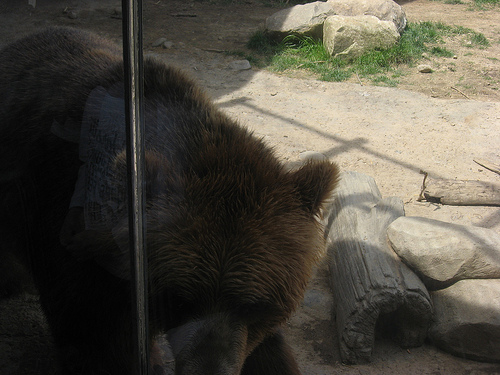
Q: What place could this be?
A: It is a zoo.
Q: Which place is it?
A: It is a zoo.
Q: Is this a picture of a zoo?
A: Yes, it is showing a zoo.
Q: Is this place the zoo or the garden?
A: It is the zoo.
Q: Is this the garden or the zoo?
A: It is the zoo.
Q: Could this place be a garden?
A: No, it is a zoo.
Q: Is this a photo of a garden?
A: No, the picture is showing a zoo.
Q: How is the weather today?
A: It is sunny.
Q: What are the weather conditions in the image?
A: It is sunny.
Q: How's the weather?
A: It is sunny.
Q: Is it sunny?
A: Yes, it is sunny.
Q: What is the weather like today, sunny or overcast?
A: It is sunny.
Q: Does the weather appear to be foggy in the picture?
A: No, it is sunny.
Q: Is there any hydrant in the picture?
A: No, there are no fire hydrants.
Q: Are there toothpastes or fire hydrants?
A: No, there are no fire hydrants or toothpastes.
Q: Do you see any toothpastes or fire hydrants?
A: No, there are no fire hydrants or toothpastes.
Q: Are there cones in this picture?
A: No, there are no cones.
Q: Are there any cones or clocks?
A: No, there are no cones or clocks.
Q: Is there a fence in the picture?
A: No, there are no fences.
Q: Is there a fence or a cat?
A: No, there are no fences or cats.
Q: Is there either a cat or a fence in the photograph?
A: No, there are no fences or cats.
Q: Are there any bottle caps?
A: No, there are no bottle caps.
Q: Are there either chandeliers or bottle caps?
A: No, there are no bottle caps or chandeliers.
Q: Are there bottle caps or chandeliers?
A: No, there are no bottle caps or chandeliers.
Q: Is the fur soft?
A: Yes, the fur is soft.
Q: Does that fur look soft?
A: Yes, the fur is soft.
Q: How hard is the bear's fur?
A: The fur is soft.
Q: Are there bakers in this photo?
A: No, there are no bakers.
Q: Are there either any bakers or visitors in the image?
A: No, there are no bakers or visitors.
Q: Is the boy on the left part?
A: Yes, the boy is on the left of the image.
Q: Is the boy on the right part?
A: No, the boy is on the left of the image.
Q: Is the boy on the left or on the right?
A: The boy is on the left of the image.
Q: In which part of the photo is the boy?
A: The boy is on the left of the image.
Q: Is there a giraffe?
A: No, there are no giraffes.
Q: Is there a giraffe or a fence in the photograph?
A: No, there are no giraffes or fences.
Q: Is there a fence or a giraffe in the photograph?
A: No, there are no giraffes or fences.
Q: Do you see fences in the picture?
A: No, there are no fences.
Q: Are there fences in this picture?
A: No, there are no fences.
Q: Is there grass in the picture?
A: Yes, there is grass.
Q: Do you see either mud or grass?
A: Yes, there is grass.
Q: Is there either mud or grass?
A: Yes, there is grass.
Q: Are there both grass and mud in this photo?
A: No, there is grass but no mud.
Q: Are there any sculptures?
A: No, there are no sculptures.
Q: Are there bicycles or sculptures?
A: No, there are no sculptures or bicycles.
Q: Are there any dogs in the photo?
A: No, there are no dogs.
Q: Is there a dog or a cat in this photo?
A: No, there are no dogs or cats.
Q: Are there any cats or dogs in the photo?
A: No, there are no dogs or cats.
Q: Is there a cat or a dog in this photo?
A: No, there are no dogs or cats.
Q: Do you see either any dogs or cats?
A: No, there are no dogs or cats.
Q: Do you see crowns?
A: No, there are no crowns.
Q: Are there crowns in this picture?
A: No, there are no crowns.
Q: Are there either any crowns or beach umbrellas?
A: No, there are no crowns or beach umbrellas.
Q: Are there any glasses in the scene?
A: No, there are no glasses.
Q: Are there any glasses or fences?
A: No, there are no glasses or fences.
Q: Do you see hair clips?
A: No, there are no hair clips.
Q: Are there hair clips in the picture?
A: No, there are no hair clips.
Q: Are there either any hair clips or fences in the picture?
A: No, there are no hair clips or fences.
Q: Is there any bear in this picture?
A: Yes, there is a bear.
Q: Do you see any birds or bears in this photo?
A: Yes, there is a bear.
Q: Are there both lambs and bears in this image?
A: No, there is a bear but no lambs.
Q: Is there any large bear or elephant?
A: Yes, there is a large bear.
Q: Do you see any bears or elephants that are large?
A: Yes, the bear is large.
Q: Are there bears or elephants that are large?
A: Yes, the bear is large.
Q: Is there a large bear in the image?
A: Yes, there is a large bear.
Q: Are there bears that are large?
A: Yes, there is a bear that is large.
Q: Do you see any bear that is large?
A: Yes, there is a bear that is large.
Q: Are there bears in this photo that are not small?
A: Yes, there is a large bear.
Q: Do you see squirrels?
A: No, there are no squirrels.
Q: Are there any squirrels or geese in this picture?
A: No, there are no squirrels or geese.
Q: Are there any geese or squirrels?
A: No, there are no squirrels or geese.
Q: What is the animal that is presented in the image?
A: The animal is a bear.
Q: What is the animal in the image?
A: The animal is a bear.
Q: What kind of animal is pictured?
A: The animal is a bear.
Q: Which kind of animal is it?
A: The animal is a bear.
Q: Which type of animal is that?
A: This is a bear.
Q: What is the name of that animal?
A: This is a bear.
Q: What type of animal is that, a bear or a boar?
A: This is a bear.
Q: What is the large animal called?
A: The animal is a bear.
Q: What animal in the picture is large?
A: The animal is a bear.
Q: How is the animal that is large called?
A: The animal is a bear.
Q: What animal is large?
A: The animal is a bear.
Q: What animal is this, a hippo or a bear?
A: This is a bear.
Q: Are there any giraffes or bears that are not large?
A: No, there is a bear but it is large.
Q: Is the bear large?
A: Yes, the bear is large.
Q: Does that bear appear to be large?
A: Yes, the bear is large.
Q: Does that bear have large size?
A: Yes, the bear is large.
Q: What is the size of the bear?
A: The bear is large.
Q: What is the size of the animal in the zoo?
A: The bear is large.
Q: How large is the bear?
A: The bear is large.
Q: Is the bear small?
A: No, the bear is large.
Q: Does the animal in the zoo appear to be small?
A: No, the bear is large.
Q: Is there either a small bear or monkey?
A: No, there is a bear but it is large.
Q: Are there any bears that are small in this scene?
A: No, there is a bear but it is large.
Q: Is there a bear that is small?
A: No, there is a bear but it is large.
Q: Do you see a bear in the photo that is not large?
A: No, there is a bear but it is large.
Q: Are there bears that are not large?
A: No, there is a bear but it is large.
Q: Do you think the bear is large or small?
A: The bear is large.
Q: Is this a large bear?
A: Yes, this is a large bear.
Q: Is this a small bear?
A: No, this is a large bear.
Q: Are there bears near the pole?
A: Yes, there is a bear near the pole.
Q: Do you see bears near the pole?
A: Yes, there is a bear near the pole.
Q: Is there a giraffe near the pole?
A: No, there is a bear near the pole.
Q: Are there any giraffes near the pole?
A: No, there is a bear near the pole.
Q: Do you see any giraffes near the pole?
A: No, there is a bear near the pole.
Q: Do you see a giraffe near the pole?
A: No, there is a bear near the pole.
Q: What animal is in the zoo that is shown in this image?
A: The bear is in the zoo.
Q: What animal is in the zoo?
A: The bear is in the zoo.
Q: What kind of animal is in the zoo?
A: The animal is a bear.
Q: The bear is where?
A: The bear is in the zoo.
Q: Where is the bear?
A: The bear is in the zoo.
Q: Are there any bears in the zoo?
A: Yes, there is a bear in the zoo.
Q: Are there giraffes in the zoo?
A: No, there is a bear in the zoo.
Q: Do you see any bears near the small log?
A: Yes, there is a bear near the log.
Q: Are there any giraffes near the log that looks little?
A: No, there is a bear near the log.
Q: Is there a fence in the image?
A: No, there are no fences.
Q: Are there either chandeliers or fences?
A: No, there are no fences or chandeliers.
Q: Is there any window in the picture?
A: Yes, there are windows.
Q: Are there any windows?
A: Yes, there are windows.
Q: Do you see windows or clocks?
A: Yes, there are windows.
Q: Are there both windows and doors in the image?
A: No, there are windows but no doors.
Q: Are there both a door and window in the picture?
A: No, there are windows but no doors.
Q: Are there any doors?
A: No, there are no doors.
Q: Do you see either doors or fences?
A: No, there are no doors or fences.